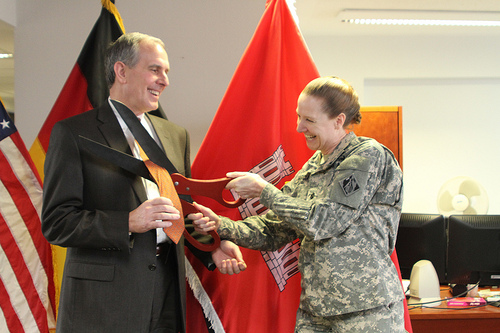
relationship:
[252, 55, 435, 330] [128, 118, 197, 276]
she cutting tie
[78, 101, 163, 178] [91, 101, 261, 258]
blades of scissors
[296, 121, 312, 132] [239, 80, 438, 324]
nose on woman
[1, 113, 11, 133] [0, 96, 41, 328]
star on flag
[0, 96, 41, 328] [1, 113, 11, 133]
flag with star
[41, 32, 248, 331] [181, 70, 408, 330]
man laughing at woman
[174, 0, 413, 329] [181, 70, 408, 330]
flag behind woman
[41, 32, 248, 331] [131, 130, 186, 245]
man holding tie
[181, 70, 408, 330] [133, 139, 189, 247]
woman cutting tie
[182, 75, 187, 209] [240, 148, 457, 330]
woman wearin uniform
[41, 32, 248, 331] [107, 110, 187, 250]
man wearing orange tie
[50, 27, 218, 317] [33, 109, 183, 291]
man wearing jacket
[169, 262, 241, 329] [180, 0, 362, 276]
fringe on flag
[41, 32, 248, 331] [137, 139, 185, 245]
man wearing orange tie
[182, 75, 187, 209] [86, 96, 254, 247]
woman holding scissors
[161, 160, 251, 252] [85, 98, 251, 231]
handles on scissors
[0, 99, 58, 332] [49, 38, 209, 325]
flag beside man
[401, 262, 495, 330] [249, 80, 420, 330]
desk beside woman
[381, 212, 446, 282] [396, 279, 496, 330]
computer monitor on desk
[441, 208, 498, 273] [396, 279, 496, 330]
computer monitor on desk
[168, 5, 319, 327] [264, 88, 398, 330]
flag behind woman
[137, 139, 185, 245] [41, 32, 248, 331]
orange tie on a man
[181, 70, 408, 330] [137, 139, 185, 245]
woman cutting a orange tie